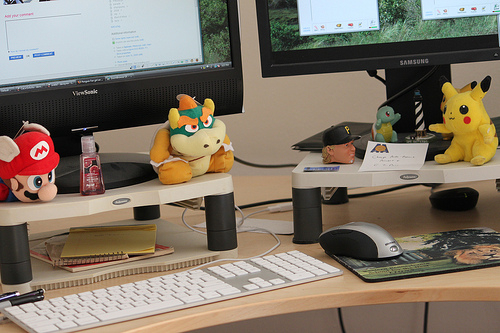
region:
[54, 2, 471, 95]
two computer monitors on desk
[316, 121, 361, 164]
doll head of baseball player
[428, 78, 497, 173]
yellow stuffed animal on stand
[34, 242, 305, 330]
white keyboard on desk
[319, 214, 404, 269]
computer mouse on pad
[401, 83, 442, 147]
small lighthouse statue under monitor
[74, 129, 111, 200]
small bottle on monitor stand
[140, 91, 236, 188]
stuffed toy with yellow horns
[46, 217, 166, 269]
pads of paper under stand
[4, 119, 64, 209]
stuffed toy with red hat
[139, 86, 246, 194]
A yellow, green, red, and orange figure is sitting on a desk.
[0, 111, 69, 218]
A red, white, brown, black, pink and green object is laying on a desk.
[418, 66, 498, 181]
A yellow, black, and red figure is sitting on a desk.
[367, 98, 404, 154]
A green, yellow, white, and red figure is sitting on a desk.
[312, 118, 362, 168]
A black, yellow, and tan figure of a head is sitting on a desk.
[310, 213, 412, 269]
A mouse is sitting on a pad.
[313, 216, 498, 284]
A pad is sitting on a desk.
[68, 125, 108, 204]
A plastic bottle is sitting on a desk.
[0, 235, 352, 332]
A keyboard is sitting on a desk.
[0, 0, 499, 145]
Two computer screens are on.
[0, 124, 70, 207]
super mario brothers stuffed animal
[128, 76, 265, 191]
a stuffed animal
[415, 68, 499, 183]
a pikachu stuffed animal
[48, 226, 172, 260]
a yellow notepad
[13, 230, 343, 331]
a white keyboard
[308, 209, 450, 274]
a silver and black mouse for a computer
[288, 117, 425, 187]
a baseball player bobble head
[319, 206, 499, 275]
a mousepad for a computer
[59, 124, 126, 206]
a bottle of hand sanitizer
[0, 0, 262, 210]
a black computer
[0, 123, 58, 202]
toy sitting on computer desk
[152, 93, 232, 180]
toy sitting on computer desk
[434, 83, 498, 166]
stuffed animal sitting on desk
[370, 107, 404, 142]
toy sitting on desk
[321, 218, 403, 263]
computer mouse laying on desk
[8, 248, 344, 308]
keyboard sitting on desk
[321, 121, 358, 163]
bobble head sitting on desk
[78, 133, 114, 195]
appliance bottle sitting on desk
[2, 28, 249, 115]
computer monitor on desk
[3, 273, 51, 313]
pens sitting on desk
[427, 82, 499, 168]
Yellow stuffed animal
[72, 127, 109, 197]
Red bottle of hand sanitizer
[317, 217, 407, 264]
Silver and black computer mouse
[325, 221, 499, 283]
Green mousepad with a lion on it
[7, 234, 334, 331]
White and silver keyboard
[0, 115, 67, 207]
Mario stuffed figurine with red hat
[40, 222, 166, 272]
Pile of notepads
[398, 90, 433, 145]
Small lighthouse statue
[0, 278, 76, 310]
Ends of black pencils and pens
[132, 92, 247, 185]
Orange and green dragon stuffed animal